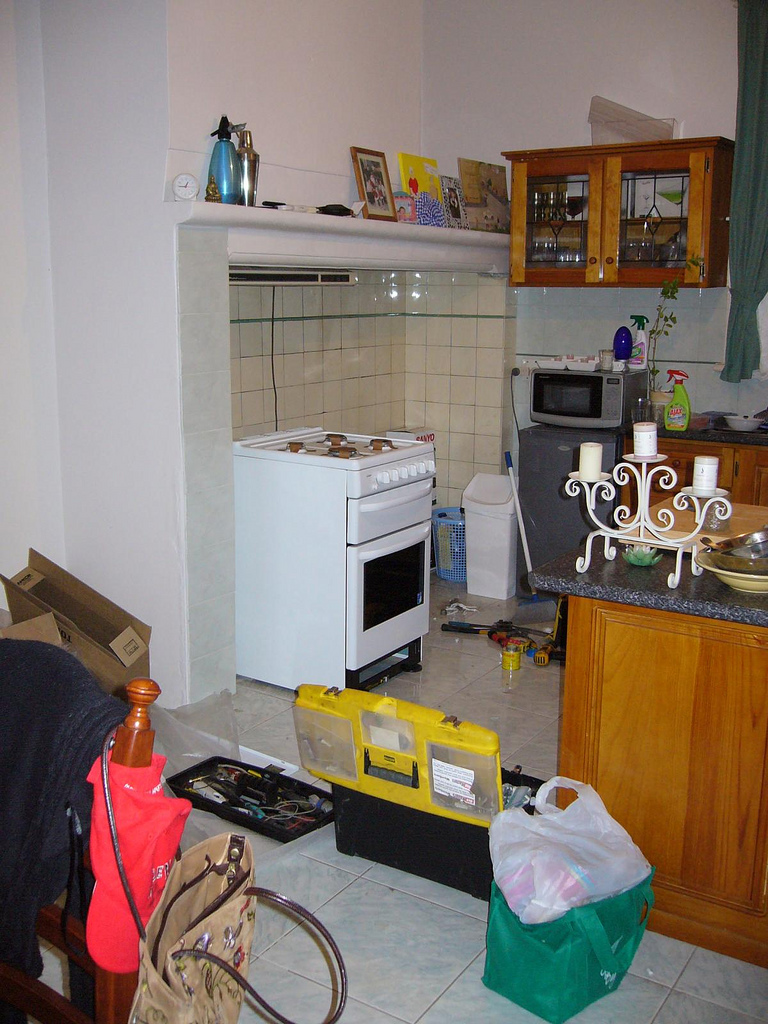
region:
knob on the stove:
[370, 477, 384, 489]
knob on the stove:
[416, 456, 432, 471]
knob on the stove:
[396, 453, 417, 474]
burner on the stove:
[283, 433, 307, 453]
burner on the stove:
[315, 429, 350, 446]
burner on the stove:
[360, 440, 395, 463]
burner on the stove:
[319, 444, 372, 470]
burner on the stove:
[318, 433, 353, 458]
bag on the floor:
[147, 965, 246, 1020]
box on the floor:
[321, 788, 451, 880]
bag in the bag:
[520, 838, 633, 898]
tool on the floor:
[433, 622, 479, 637]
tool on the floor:
[500, 632, 549, 653]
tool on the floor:
[421, 587, 471, 618]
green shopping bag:
[476, 857, 663, 1022]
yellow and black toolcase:
[288, 678, 551, 907]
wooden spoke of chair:
[112, 668, 166, 733]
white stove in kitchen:
[233, 419, 443, 703]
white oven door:
[346, 514, 440, 673]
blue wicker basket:
[426, 496, 475, 590]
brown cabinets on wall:
[490, 122, 740, 300]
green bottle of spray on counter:
[651, 364, 699, 435]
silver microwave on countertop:
[519, 360, 660, 440]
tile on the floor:
[638, 948, 696, 969]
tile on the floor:
[708, 962, 739, 991]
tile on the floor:
[672, 1006, 706, 1019]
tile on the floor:
[367, 936, 398, 977]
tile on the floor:
[321, 848, 351, 860]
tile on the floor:
[300, 881, 317, 898]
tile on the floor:
[468, 697, 507, 715]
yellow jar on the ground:
[494, 640, 525, 680]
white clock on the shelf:
[169, 167, 200, 206]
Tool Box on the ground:
[283, 671, 555, 910]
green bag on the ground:
[485, 867, 670, 1017]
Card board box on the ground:
[4, 535, 158, 688]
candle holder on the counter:
[554, 417, 725, 590]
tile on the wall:
[236, 290, 497, 429]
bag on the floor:
[449, 777, 650, 1015]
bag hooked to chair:
[80, 670, 346, 1018]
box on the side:
[10, 528, 163, 699]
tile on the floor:
[302, 847, 477, 1013]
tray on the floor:
[153, 727, 336, 852]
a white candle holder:
[550, 421, 728, 597]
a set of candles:
[557, 412, 732, 517]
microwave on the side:
[514, 338, 632, 429]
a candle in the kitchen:
[566, 409, 603, 490]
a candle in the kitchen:
[632, 428, 662, 494]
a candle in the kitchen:
[689, 442, 764, 501]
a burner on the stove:
[334, 431, 350, 461]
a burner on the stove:
[363, 421, 391, 457]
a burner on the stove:
[307, 413, 355, 449]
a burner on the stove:
[253, 436, 310, 472]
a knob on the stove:
[370, 469, 391, 485]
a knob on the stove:
[385, 461, 394, 480]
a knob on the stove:
[398, 452, 417, 480]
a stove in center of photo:
[227, 413, 448, 694]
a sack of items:
[490, 774, 660, 1012]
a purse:
[104, 833, 313, 1021]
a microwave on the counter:
[523, 336, 652, 438]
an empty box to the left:
[7, 542, 167, 701]